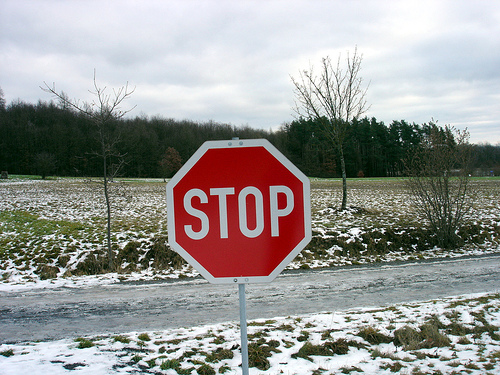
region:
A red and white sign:
[161, 133, 328, 290]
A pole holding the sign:
[234, 280, 256, 374]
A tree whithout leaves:
[38, 65, 143, 274]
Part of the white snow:
[10, 359, 40, 369]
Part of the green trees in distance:
[26, 123, 54, 156]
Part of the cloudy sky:
[168, 33, 244, 80]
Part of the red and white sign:
[219, 247, 257, 264]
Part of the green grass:
[26, 218, 38, 233]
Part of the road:
[17, 303, 108, 323]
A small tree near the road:
[392, 122, 483, 254]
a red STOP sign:
[140, 128, 318, 282]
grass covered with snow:
[34, 178, 125, 233]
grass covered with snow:
[319, 195, 396, 249]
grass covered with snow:
[282, 311, 433, 372]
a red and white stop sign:
[169, 136, 313, 281]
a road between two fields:
[0, 255, 499, 340]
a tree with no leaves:
[40, 66, 137, 272]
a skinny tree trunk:
[341, 153, 347, 214]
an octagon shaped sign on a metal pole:
[162, 139, 312, 373]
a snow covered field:
[0, 293, 499, 373]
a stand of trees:
[0, 108, 499, 177]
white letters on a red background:
[183, 186, 292, 236]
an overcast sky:
[0, 3, 498, 146]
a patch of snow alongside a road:
[1, 272, 110, 289]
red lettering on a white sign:
[181, 183, 295, 243]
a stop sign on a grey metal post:
[167, 135, 309, 373]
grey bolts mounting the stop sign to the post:
[230, 276, 252, 286]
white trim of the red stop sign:
[298, 174, 313, 245]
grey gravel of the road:
[76, 293, 184, 330]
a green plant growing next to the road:
[405, 155, 478, 257]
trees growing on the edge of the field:
[15, 113, 216, 187]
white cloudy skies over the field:
[142, 22, 287, 112]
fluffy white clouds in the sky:
[152, 14, 256, 107]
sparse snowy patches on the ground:
[15, 187, 95, 255]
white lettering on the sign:
[176, 183, 291, 246]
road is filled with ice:
[103, 265, 493, 300]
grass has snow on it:
[312, 302, 499, 372]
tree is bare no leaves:
[316, 60, 350, 235]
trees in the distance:
[0, 127, 190, 173]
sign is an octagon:
[170, 145, 313, 275]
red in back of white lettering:
[185, 147, 278, 277]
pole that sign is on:
[225, 286, 266, 362]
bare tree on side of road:
[408, 127, 461, 244]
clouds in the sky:
[141, 38, 288, 114]